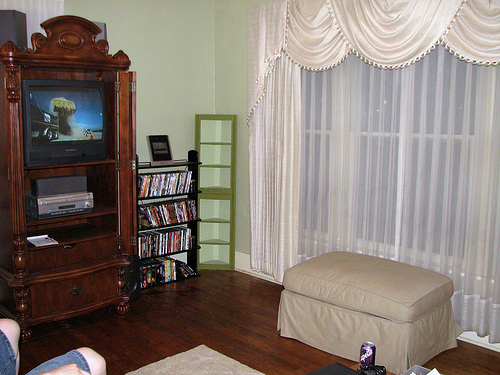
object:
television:
[21, 74, 113, 170]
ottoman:
[274, 250, 458, 374]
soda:
[358, 340, 376, 370]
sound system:
[26, 176, 94, 222]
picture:
[146, 135, 175, 167]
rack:
[192, 113, 237, 273]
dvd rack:
[137, 155, 204, 294]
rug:
[120, 342, 271, 375]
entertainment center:
[3, 13, 152, 341]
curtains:
[244, 0, 499, 345]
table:
[301, 360, 378, 374]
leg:
[0, 318, 21, 375]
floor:
[192, 284, 250, 337]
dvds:
[138, 170, 192, 199]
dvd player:
[26, 191, 93, 221]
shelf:
[18, 207, 118, 229]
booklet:
[25, 233, 58, 247]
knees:
[71, 346, 107, 372]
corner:
[204, 44, 230, 90]